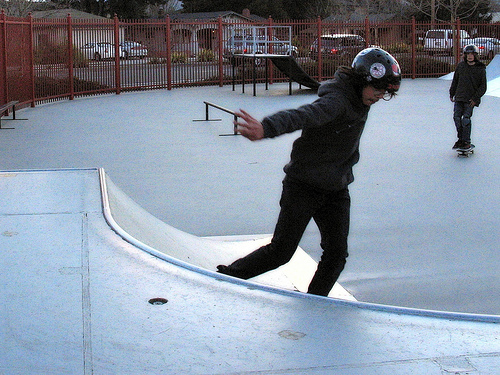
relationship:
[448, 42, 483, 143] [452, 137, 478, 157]
boy on skateboard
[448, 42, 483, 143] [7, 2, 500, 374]
boy at skatepark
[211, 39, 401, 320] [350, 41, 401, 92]
boy wearing helmet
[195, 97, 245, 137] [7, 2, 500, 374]
grinding rail at skatepark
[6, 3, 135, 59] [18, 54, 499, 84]
house across street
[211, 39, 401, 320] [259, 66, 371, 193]
boy wearing shirt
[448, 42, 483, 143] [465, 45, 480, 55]
boy in helmet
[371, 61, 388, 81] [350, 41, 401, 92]
sticker on helmet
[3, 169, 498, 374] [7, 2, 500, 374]
ramp at skatepark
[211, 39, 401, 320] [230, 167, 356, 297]
boy wearing jeans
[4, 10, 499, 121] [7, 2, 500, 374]
fence around skatepark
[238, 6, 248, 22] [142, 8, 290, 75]
chimmney on house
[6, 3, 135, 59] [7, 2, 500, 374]
house behind skatepark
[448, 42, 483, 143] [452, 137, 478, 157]
boy with skateboard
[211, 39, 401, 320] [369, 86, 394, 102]
boy with reading glasses